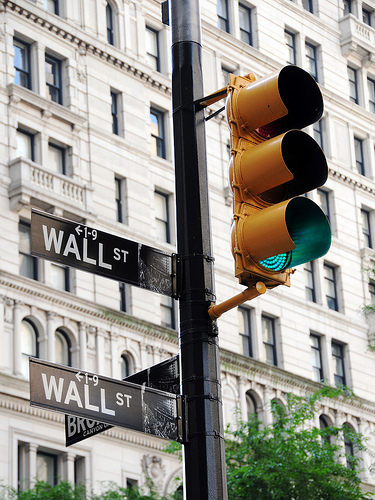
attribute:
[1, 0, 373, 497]
building — white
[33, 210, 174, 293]
sign — one, metal, black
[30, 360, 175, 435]
sign — one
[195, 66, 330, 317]
traffic light — one, yellow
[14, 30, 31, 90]
window — closed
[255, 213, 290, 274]
light — green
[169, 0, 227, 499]
pole — metal, black, straight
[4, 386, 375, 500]
shrubs — green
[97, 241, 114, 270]
letter — white